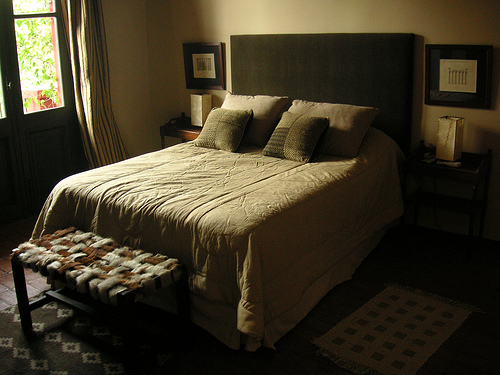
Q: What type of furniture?
A: Bed.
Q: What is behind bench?
A: Bed.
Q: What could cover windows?
A: Drapes.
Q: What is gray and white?
A: Rug.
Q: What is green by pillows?
A: Headboard.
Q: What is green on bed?
A: Pillows.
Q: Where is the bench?
A: At the foot of the bed.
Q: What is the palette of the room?
A: Earth tones.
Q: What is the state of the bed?
A: It is perfectly made.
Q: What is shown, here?
A: A bedroom .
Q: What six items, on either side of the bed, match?
A: The nightstands, the lamps, and the mounted, framed pictures.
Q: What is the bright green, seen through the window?
A: Leaves, growing outside.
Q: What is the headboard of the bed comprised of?
A: Wood.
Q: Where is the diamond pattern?
A: On the rug, under the bench.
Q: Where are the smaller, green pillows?
A: Propped, in front of the larger, tan ones.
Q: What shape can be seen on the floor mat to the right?
A: Tiny squares.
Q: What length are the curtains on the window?
A: Floor length.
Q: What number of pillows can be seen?
A: Four.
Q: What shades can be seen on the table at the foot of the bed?
A: Brown and white.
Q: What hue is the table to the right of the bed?
A: Dark brown.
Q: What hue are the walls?
A: They are light tan.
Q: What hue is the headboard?
A: Dark green.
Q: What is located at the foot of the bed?
A: A bench.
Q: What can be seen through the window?
A: A plant and part of a building.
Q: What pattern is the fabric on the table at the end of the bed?
A: It is woven.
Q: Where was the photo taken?
A: Bedroom.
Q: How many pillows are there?
A: Four.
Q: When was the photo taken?
A: Daytime.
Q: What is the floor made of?
A: Tiles.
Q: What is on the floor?
A: A rug.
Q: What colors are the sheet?
A: Cream.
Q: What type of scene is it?
A: Indoor.